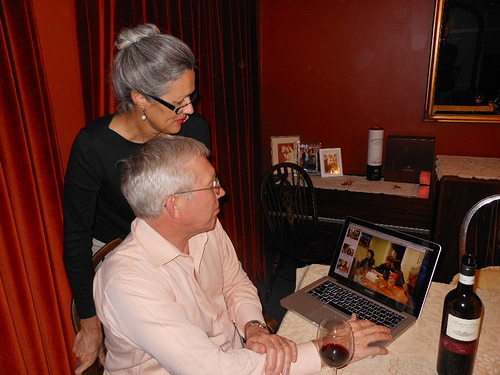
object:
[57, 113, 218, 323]
shirt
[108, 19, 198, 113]
gray hair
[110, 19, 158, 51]
bun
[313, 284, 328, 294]
black key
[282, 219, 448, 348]
laptop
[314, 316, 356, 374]
glass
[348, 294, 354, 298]
key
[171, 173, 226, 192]
eyeglasses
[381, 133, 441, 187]
nick knack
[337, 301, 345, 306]
keys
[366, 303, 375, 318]
black key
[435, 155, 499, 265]
wooden cabinet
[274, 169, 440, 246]
wooden cabinet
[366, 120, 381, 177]
nick knack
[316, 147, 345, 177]
nick knack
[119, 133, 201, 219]
hair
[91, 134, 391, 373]
man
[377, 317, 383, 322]
key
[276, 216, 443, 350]
computer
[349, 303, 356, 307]
key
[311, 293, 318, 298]
key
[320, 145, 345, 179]
knick knack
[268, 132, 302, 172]
nick knack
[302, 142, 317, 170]
nick knack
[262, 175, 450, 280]
cabinet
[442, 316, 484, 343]
label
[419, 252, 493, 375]
wine bottle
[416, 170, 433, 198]
nick knack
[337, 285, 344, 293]
black key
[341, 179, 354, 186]
knack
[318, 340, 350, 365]
wine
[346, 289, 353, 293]
key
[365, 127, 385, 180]
knick knack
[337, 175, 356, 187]
knick knack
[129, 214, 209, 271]
collar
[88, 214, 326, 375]
collarshirt